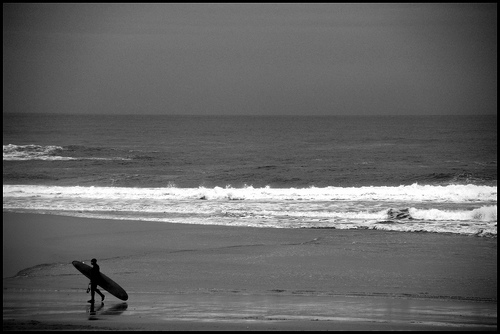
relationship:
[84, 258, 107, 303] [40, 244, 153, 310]
man carrying surfboard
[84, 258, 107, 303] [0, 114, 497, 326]
man walking on beach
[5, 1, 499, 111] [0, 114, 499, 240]
sky above water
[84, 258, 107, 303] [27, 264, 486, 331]
man on beach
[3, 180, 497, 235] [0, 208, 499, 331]
wave crashing on beach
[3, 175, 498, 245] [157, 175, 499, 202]
wave creating foam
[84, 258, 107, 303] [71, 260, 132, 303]
man holding surfboard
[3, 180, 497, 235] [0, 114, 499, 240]
wave on water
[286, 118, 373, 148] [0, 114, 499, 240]
water in water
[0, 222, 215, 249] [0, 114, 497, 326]
sand on beach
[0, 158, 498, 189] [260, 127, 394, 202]
ripples in water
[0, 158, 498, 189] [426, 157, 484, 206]
ripples on water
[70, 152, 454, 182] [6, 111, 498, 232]
ripples on water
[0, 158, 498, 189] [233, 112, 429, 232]
ripples on water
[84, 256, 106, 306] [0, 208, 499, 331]
man walking on beach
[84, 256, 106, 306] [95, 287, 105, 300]
man has leg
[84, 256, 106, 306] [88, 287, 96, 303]
man has leg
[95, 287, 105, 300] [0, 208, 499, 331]
leg walking on beach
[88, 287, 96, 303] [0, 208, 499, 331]
leg walking on beach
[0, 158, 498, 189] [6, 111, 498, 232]
ripples in water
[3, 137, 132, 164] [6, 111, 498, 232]
ripples in water